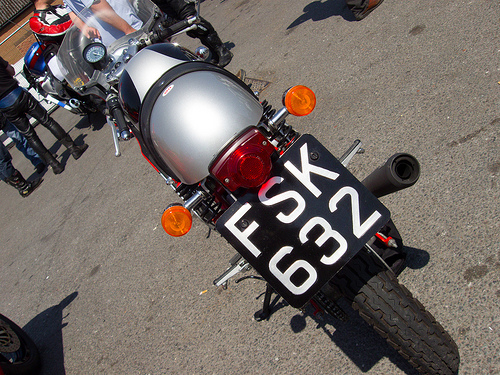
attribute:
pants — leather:
[3, 89, 78, 169]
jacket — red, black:
[30, 14, 80, 46]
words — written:
[223, 143, 380, 294]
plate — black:
[211, 130, 391, 310]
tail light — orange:
[157, 200, 198, 237]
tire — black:
[310, 253, 460, 365]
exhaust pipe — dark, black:
[357, 149, 429, 194]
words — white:
[200, 142, 317, 240]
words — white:
[269, 185, 391, 267]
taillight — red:
[163, 81, 319, 238]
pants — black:
[4, 82, 89, 174]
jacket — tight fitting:
[30, 5, 76, 42]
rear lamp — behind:
[202, 122, 280, 198]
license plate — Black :
[209, 127, 396, 313]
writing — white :
[220, 137, 385, 299]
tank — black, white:
[113, 35, 199, 115]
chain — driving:
[308, 292, 350, 321]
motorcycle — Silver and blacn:
[19, 23, 499, 370]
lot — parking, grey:
[10, 38, 498, 368]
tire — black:
[331, 245, 473, 373]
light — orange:
[281, 82, 317, 118]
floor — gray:
[27, 23, 494, 353]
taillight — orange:
[283, 84, 316, 117]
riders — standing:
[2, 60, 87, 202]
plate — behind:
[224, 157, 416, 297]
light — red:
[193, 121, 282, 207]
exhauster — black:
[284, 156, 422, 198]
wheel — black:
[321, 247, 463, 372]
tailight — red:
[274, 80, 329, 127]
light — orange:
[162, 206, 191, 238]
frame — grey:
[148, 73, 266, 184]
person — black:
[1, 57, 91, 172]